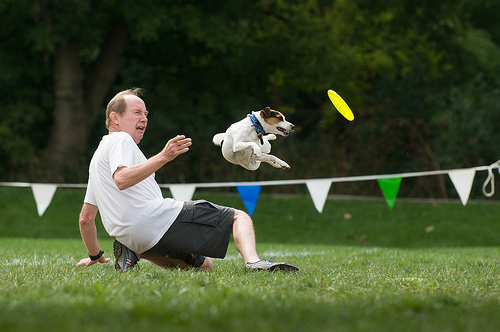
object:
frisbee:
[327, 90, 358, 122]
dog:
[213, 106, 295, 171]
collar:
[247, 109, 266, 137]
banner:
[447, 170, 475, 207]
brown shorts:
[158, 197, 234, 260]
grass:
[300, 202, 498, 331]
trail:
[226, 189, 498, 206]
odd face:
[117, 94, 150, 142]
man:
[78, 89, 300, 275]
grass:
[1, 271, 500, 330]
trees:
[451, 2, 500, 89]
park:
[1, 0, 498, 331]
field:
[0, 186, 500, 330]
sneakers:
[109, 240, 140, 272]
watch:
[89, 249, 105, 260]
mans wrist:
[85, 245, 110, 265]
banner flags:
[373, 175, 406, 211]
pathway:
[251, 185, 499, 210]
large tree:
[2, 2, 98, 186]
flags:
[305, 181, 333, 213]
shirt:
[86, 132, 184, 253]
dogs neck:
[250, 111, 275, 142]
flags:
[31, 186, 58, 216]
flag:
[237, 185, 262, 215]